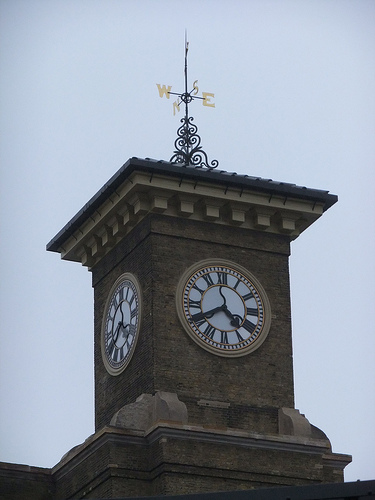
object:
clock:
[175, 256, 273, 359]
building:
[0, 155, 374, 499]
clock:
[100, 271, 142, 376]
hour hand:
[221, 306, 240, 328]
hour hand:
[117, 321, 131, 333]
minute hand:
[189, 305, 223, 322]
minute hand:
[107, 321, 122, 355]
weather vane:
[155, 28, 218, 168]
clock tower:
[45, 155, 339, 450]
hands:
[189, 304, 222, 322]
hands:
[107, 323, 120, 352]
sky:
[0, 0, 374, 480]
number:
[216, 271, 227, 285]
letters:
[156, 80, 216, 115]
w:
[155, 82, 172, 99]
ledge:
[51, 423, 352, 484]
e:
[202, 91, 215, 109]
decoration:
[46, 156, 338, 271]